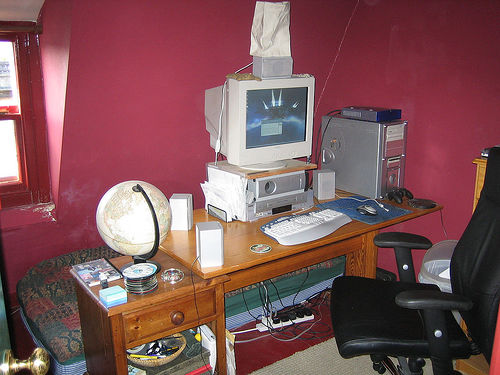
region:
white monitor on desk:
[205, 74, 342, 195]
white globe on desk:
[94, 185, 154, 256]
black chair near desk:
[315, 150, 490, 362]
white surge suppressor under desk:
[247, 303, 317, 336]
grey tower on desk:
[322, 110, 400, 202]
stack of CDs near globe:
[119, 257, 165, 309]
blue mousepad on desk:
[317, 192, 400, 229]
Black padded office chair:
[331, 142, 499, 371]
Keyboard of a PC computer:
[258, 209, 354, 243]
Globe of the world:
[96, 178, 179, 263]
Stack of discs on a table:
[123, 257, 165, 297]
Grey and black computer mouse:
[356, 201, 383, 218]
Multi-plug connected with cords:
[252, 300, 321, 335]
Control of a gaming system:
[386, 186, 418, 203]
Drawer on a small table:
[108, 283, 227, 342]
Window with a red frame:
[1, 55, 58, 198]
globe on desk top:
[92, 176, 172, 271]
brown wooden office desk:
[66, 170, 453, 371]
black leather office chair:
[328, 143, 495, 373]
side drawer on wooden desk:
[119, 285, 219, 344]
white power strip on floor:
[253, 299, 315, 333]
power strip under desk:
[253, 300, 320, 332]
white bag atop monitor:
[247, 0, 299, 60]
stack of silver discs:
[119, 261, 162, 296]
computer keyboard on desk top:
[258, 206, 353, 248]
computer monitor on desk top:
[195, 68, 317, 170]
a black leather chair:
[327, 153, 492, 369]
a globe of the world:
[91, 178, 173, 259]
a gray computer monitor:
[195, 77, 324, 166]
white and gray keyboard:
[259, 209, 355, 247]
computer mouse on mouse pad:
[335, 194, 413, 225]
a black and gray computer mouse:
[351, 198, 383, 220]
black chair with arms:
[322, 145, 495, 364]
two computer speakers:
[165, 191, 228, 275]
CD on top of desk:
[245, 237, 278, 259]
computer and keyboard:
[183, 74, 355, 246]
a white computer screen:
[166, 49, 329, 177]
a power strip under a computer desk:
[234, 271, 351, 355]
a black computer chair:
[316, 149, 498, 374]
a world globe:
[72, 183, 236, 304]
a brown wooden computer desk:
[125, 178, 433, 327]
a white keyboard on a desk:
[251, 199, 357, 250]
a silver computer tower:
[304, 83, 451, 215]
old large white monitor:
[205, 80, 313, 155]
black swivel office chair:
[338, 240, 498, 351]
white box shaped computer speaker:
[194, 220, 226, 268]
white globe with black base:
[99, 178, 170, 260]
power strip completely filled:
[259, 309, 313, 322]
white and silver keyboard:
[261, 216, 348, 236]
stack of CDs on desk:
[124, 265, 163, 292]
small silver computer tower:
[318, 110, 416, 206]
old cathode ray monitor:
[203, 65, 362, 175]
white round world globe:
[83, 165, 185, 273]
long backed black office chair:
[319, 142, 492, 373]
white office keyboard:
[272, 200, 352, 256]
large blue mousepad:
[294, 192, 410, 246]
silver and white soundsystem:
[218, 147, 330, 214]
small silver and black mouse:
[355, 191, 379, 220]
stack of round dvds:
[115, 250, 164, 299]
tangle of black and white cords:
[208, 263, 328, 365]